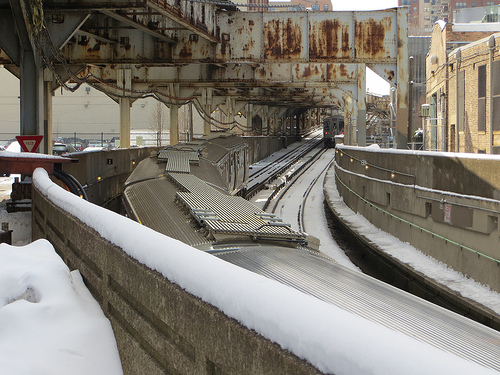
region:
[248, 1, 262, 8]
;part of a building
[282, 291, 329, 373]
poart of a snow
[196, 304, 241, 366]
part of a wall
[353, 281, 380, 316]
part of a train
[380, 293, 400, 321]
top of a train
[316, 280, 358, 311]
part of a train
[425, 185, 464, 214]
[part of a wall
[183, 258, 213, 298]
part of a wall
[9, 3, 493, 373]
trains are on the tracks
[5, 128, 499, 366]
the tracks and walls are covered in snow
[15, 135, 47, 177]
a yield sign is near the tracks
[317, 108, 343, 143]
the brake lights are on the train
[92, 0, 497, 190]
the tracks are surrounded by buildings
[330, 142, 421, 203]
lights are on the wall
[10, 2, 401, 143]
the overpass is steel and rusted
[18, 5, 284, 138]
wires are roped under the overpass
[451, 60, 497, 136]
windows are blocked next to the tracks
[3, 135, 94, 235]
cables are going over the wall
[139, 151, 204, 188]
top of gray passenger train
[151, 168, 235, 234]
top of gray passenger train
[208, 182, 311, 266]
top of gray passenger train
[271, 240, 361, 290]
top of gray passenger train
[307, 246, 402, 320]
top of gray passenger train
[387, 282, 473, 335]
top of gray passenger train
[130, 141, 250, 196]
top of gray passenger train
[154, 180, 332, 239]
top of gray passenger train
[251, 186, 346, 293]
top of gray passenger train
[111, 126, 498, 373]
silver train passing around the corner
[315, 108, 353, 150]
train going in the opposite direction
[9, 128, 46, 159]
red and white yield sign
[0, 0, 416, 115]
rust covered metal beams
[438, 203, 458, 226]
white warning sign next to the tracks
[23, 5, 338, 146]
chains that hang by the tracks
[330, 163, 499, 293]
hand rail on the wall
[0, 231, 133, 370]
pile of snow on the other side of the wall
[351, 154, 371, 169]
black and white warning sign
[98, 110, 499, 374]
two trains passing each other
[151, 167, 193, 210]
top of gray passenger train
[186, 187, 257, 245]
top of gray passenger train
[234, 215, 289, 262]
top of gray passenger train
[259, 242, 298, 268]
top of gray passenger train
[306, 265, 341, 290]
top of gray passenger train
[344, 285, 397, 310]
top of gray passenger train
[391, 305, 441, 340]
top of gray passenger train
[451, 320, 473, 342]
top of gray passenger train